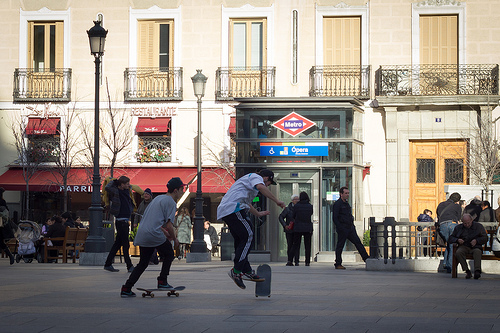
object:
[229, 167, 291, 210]
skateboarder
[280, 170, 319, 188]
door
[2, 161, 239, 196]
awning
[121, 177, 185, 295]
man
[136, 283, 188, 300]
skateboard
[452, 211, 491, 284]
man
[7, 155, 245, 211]
red awning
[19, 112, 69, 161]
window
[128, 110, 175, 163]
window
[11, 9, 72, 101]
window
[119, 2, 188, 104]
window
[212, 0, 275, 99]
window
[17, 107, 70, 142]
red awning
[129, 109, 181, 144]
red awning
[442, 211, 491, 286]
man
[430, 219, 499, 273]
bench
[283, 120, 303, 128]
metro sign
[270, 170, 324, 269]
entrance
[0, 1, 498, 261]
building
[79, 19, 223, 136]
lights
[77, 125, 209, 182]
poles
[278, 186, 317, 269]
people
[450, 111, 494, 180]
tree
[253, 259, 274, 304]
skateboard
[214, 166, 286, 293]
skateboarder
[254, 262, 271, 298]
skateboard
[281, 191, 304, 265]
person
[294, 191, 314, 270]
person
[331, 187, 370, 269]
person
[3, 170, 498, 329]
public place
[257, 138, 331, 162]
sign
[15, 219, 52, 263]
carriage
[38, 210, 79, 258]
woman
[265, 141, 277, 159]
bed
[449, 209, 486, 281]
man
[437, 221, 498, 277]
bench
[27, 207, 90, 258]
people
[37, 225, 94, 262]
bench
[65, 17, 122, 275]
street lamp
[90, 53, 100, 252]
pole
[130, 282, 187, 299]
skateboard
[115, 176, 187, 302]
skateboarder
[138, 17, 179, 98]
window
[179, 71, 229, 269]
streetlamp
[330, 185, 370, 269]
man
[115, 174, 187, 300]
man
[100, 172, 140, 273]
man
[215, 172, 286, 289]
man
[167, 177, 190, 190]
hat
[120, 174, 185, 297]
boy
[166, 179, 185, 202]
head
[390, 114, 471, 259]
doors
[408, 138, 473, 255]
doors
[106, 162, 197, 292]
man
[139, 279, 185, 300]
skateboard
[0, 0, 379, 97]
windows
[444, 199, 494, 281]
man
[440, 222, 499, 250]
bench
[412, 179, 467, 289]
man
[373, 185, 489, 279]
bench